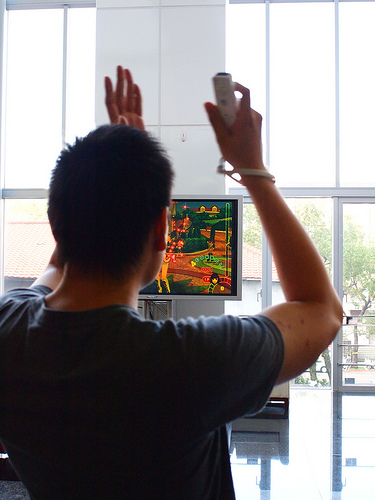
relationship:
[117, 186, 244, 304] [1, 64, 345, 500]
tv in front of person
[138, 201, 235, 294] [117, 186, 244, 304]
game on tv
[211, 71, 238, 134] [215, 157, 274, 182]
remote has lanyard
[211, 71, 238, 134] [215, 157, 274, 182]
remote with lanyard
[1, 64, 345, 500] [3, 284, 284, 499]
person wearing shirt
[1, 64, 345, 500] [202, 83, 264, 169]
person with hands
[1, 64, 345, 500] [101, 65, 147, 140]
person with hands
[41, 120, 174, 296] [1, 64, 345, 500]
head of person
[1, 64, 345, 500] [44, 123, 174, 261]
person has hair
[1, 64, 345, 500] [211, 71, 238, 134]
person holding remote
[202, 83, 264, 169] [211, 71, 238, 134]
hands holding remote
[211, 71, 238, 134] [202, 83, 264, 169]
remote in hands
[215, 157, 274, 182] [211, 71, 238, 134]
lanyard for remote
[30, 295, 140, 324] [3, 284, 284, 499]
collar on shirt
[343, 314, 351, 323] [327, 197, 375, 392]
handle on door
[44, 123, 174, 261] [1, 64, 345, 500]
hair of person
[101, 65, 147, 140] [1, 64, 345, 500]
hands of person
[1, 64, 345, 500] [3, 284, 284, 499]
person in shirt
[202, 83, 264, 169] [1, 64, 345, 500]
hands of person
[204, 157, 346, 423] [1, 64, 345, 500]
arm of person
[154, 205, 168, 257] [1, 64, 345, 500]
ear of person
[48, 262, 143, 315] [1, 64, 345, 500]
neck of person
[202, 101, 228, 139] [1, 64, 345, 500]
thumb of person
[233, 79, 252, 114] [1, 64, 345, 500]
finger of person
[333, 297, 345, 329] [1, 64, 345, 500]
elbow of person